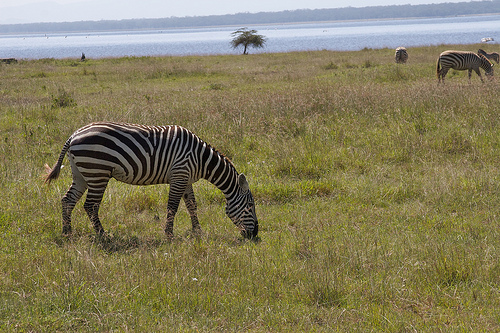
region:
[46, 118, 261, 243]
zebra grazing in field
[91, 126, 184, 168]
zebra is black and white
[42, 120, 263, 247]
zebra has stripes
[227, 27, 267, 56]
tree at edge of field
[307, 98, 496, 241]
green grass in field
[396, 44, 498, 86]
three zebras grazing in field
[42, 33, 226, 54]
ocean in background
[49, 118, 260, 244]
zebra is facing right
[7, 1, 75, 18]
hazy blue sky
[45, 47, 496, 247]
herd of zebras grazing in field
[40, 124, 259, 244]
Wild zebra feeding on open plain.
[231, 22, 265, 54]
Single tree lining shore.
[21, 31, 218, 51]
Water from lake reflecting the sun.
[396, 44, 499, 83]
Group of zebra feeding in the open.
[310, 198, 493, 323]
section of grass from meadow.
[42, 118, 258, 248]
Zebra with tail waving in the wind.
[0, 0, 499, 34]
Trees lining the shore.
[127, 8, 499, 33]
Sandy beach of the shore.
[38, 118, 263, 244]
One side of a zebra in the wild.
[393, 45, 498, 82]
Three zebras feeding in the meadow.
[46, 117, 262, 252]
a zebra eating some grass during the day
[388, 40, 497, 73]
more zebras eating some grass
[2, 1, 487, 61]
a large body of water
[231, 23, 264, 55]
a tree next to the shore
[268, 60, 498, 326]
a large amount of grass to eat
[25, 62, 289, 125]
even more grass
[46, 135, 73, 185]
a zebra tail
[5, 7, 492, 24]
a whole lot of trees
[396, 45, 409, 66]
it is a zebra butt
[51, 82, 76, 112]
a little bush in the grass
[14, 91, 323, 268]
Zebra on the grass.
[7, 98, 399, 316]
Black and white zebra on the grass.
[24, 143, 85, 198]
Tail on the back of the zebra.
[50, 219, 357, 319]
Green grass on the field.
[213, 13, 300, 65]
Tree on the plains.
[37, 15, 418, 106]
Blue water in the background.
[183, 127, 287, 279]
Zebra eating the grass.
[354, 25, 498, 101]
Zebras in the background.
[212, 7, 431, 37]
Trees by the water.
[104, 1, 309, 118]
Blue sky behind the water.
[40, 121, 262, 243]
a zebra grazing on the plain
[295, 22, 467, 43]
a river flowing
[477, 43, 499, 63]
a young zebra near it's mother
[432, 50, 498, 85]
the mother zebra grazing near it's baby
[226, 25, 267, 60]
a lone tree on the plains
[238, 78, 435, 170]
a vast, grassy field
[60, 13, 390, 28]
land on the other side of the river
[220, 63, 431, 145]
hilly terrain on the plain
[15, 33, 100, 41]
fishing traps floating in the river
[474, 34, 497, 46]
a rock in the water